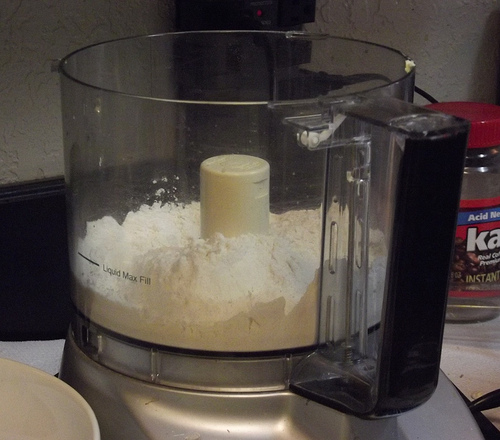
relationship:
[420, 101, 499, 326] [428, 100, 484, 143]
bottle has top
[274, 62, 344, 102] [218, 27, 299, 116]
plug plugged into wall socket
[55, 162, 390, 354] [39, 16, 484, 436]
flour in blender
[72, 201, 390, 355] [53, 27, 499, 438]
flour in mixer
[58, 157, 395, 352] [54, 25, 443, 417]
powder in mixer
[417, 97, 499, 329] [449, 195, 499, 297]
bottle has label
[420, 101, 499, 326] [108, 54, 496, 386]
bottle behind blender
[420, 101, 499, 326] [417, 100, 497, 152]
bottle with top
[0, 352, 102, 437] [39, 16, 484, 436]
bowl next to blender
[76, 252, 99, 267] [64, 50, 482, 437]
black line on blender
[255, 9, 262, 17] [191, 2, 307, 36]
button on surface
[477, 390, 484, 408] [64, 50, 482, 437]
cording from blender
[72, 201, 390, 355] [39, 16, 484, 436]
flour in blender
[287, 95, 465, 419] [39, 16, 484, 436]
handle on blender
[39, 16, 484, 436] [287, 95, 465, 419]
blender with handle